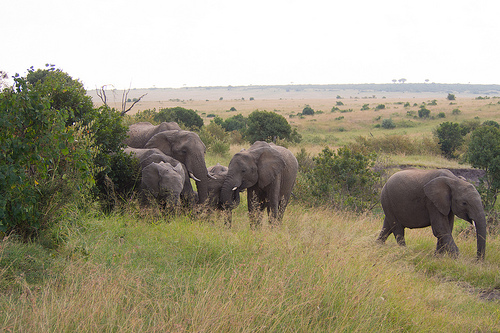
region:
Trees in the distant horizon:
[386, 69, 449, 95]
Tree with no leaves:
[93, 77, 152, 122]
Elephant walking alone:
[372, 152, 494, 280]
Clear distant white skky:
[3, 2, 498, 96]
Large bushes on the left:
[0, 53, 137, 274]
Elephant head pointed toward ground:
[141, 154, 193, 229]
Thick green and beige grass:
[81, 220, 380, 331]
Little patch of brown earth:
[383, 151, 496, 193]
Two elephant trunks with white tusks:
[179, 155, 247, 210]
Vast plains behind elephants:
[108, 82, 495, 142]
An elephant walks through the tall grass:
[365, 146, 490, 270]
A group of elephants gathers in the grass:
[91, 101, 313, 243]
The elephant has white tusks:
[361, 137, 488, 280]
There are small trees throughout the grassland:
[27, 75, 449, 315]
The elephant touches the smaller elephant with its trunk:
[208, 135, 312, 244]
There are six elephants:
[105, 100, 489, 291]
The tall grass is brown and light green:
[11, 183, 488, 325]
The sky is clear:
[236, 56, 463, 123]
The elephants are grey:
[101, 84, 489, 281]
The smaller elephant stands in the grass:
[120, 142, 192, 224]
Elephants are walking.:
[115, 125, 492, 271]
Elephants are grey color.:
[156, 140, 494, 244]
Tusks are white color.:
[179, 158, 243, 197]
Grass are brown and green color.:
[95, 246, 307, 309]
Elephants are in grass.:
[131, 140, 335, 252]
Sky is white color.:
[91, 23, 346, 70]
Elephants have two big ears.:
[232, 150, 298, 199]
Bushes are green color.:
[14, 79, 78, 209]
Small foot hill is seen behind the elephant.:
[187, 74, 494, 94]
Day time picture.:
[33, 43, 465, 323]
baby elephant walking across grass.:
[358, 159, 498, 285]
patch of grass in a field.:
[230, 256, 315, 293]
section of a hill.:
[240, 66, 340, 111]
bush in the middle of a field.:
[31, 128, 92, 241]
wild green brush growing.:
[312, 142, 375, 213]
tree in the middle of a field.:
[238, 94, 298, 141]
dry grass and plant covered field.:
[130, 85, 240, 150]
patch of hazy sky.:
[140, 19, 291, 45]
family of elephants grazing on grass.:
[99, 109, 496, 313]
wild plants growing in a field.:
[297, 90, 380, 145]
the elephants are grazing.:
[96, 90, 466, 260]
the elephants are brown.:
[111, 97, 292, 218]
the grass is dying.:
[76, 205, 403, 322]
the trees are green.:
[1, 76, 111, 238]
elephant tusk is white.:
[220, 175, 241, 191]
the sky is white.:
[43, 30, 479, 78]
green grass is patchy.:
[86, 182, 296, 297]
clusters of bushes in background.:
[188, 86, 486, 144]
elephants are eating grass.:
[105, 111, 326, 226]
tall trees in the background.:
[374, 62, 459, 101]